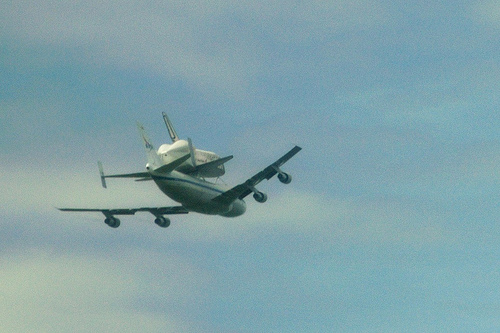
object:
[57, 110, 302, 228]
plane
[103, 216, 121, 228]
engine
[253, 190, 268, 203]
engine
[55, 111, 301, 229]
space shuttle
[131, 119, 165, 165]
tail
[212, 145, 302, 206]
wing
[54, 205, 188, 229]
wing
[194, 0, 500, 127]
sky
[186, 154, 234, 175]
wing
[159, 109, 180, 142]
tail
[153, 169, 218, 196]
strip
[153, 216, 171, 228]
engines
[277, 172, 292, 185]
engines